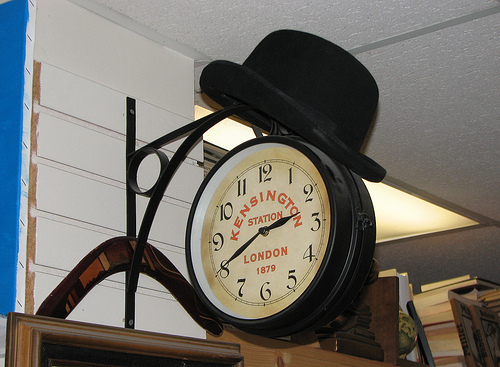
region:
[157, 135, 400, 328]
one clock is seen.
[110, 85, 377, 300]
clock is black and cream color.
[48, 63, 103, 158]
wall is white color.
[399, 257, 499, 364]
books are arranged in shelf.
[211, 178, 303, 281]
letters are in red.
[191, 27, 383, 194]
hat is on the clock.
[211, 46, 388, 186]
hat is black color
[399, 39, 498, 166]
ceiling is white color.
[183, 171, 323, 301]
time shown is 2.40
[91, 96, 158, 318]
clock is attached to the wall.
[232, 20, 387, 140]
this is a hat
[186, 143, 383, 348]
this is a clock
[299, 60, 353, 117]
the hat is black in color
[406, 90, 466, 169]
this is the ceiling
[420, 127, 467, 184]
the ceiling is white in color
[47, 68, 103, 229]
the wall is made of wood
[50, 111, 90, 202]
the wall is white in color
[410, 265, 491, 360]
these are some books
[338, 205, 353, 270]
the clock's case in black in color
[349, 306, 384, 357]
this is a sculpture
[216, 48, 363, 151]
Black felt hat resting on clock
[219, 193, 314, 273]
Antiqued paper clock face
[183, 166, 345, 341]
Antique clock with black numbers and red letters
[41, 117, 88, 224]
White rectangular wall panels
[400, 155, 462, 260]
Yellow light on ceiling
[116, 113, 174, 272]
Iron pole holding clock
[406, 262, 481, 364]
Pile of wooden items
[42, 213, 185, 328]
Wooden booomarang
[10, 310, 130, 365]
Brown picture frame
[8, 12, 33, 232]
Blue masking tape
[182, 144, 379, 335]
Black clock that says Kensington on it.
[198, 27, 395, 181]
Black hat on a clock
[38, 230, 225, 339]
Boomerang close to a clock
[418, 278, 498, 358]
Various books stacked up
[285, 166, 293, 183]
The number 1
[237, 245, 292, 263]
Orange writing that says London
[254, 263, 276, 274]
1879 in orange numbers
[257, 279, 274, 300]
The number 6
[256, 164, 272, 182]
A black number 12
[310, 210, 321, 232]
The number 3 in black color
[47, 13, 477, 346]
hat on top of a clock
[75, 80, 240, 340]
metal supporting rod for clock face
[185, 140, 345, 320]
red printing on clock face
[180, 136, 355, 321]
tan clock face with black numbers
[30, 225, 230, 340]
boomerang resting on metal support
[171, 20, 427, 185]
curved black hat with curled brim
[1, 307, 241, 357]
wooden edge of frame below clock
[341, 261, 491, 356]
books and round object on top of surface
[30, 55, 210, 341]
row of white wooden panels on wall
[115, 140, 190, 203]
circle between a corner and a curve